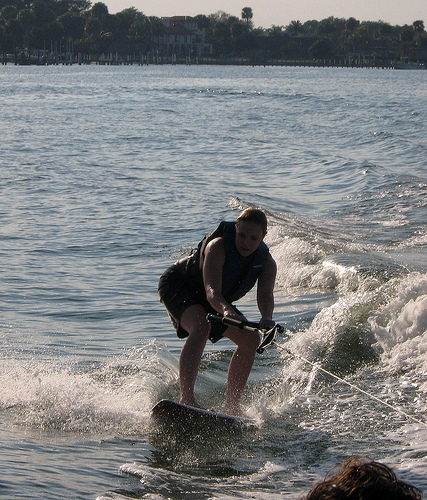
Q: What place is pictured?
A: It is a lake.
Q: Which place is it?
A: It is a lake.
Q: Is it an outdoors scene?
A: Yes, it is outdoors.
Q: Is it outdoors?
A: Yes, it is outdoors.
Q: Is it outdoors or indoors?
A: It is outdoors.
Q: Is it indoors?
A: No, it is outdoors.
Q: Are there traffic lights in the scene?
A: No, there are no traffic lights.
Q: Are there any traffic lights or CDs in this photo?
A: No, there are no traffic lights or cds.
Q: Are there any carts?
A: No, there are no carts.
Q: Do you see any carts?
A: No, there are no carts.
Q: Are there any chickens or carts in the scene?
A: No, there are no carts or chickens.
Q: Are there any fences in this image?
A: No, there are no fences.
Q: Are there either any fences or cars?
A: No, there are no fences or cars.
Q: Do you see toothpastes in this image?
A: No, there are no toothpastes.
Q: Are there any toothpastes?
A: No, there are no toothpastes.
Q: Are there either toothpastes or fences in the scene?
A: No, there are no toothpastes or fences.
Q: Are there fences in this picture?
A: No, there are no fences.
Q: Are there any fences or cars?
A: No, there are no fences or cars.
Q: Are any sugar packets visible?
A: No, there are no sugar packets.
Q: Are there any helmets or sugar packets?
A: No, there are no sugar packets or helmets.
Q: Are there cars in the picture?
A: No, there are no cars.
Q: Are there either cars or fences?
A: No, there are no cars or fences.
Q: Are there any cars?
A: No, there are no cars.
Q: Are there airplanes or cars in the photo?
A: No, there are no cars or airplanes.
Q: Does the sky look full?
A: Yes, the sky is full.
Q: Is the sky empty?
A: No, the sky is full.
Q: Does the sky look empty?
A: No, the sky is full.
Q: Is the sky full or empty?
A: The sky is full.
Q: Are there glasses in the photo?
A: No, there are no glasses.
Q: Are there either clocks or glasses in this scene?
A: No, there are no glasses or clocks.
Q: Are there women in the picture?
A: Yes, there is a woman.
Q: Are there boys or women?
A: Yes, there is a woman.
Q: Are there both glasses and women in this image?
A: No, there is a woman but no glasses.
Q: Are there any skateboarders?
A: No, there are no skateboarders.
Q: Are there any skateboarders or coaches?
A: No, there are no skateboarders or coaches.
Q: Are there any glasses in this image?
A: No, there are no glasses.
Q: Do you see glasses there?
A: No, there are no glasses.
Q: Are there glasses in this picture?
A: No, there are no glasses.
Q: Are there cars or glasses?
A: No, there are no glasses or cars.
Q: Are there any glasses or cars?
A: No, there are no glasses or cars.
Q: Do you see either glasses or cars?
A: No, there are no glasses or cars.